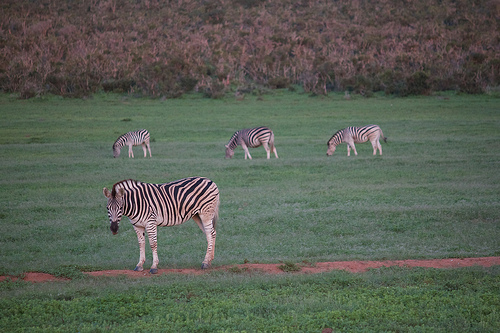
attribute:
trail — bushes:
[308, 258, 348, 272]